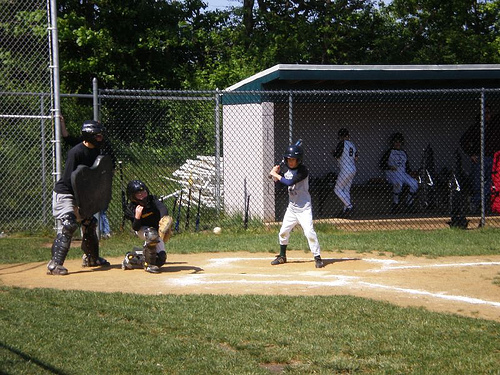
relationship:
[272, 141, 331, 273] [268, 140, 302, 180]
boy holding bat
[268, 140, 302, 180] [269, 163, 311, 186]
bat on right shoulder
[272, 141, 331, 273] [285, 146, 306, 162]
boy wears helmet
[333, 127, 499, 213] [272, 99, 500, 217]
baseball players in rest area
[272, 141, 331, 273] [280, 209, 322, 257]
boy wears pants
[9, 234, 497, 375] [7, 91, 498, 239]
field has fence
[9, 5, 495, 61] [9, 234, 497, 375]
trees behind field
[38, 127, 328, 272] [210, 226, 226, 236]
boys playing baseball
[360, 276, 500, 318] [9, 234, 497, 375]
lines drawn in ground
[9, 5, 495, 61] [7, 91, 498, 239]
trees behind fence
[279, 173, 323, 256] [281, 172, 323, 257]
players in white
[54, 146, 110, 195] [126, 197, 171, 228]
players dress in black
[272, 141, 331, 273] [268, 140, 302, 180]
boy swings baseballbat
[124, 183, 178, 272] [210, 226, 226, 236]
catcher waiting for ball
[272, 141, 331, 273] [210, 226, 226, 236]
boy playing baseball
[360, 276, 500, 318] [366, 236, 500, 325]
lines in dirt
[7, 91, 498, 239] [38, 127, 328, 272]
page fence behind players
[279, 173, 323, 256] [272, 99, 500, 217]
players in dugout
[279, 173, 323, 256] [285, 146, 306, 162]
players have helmet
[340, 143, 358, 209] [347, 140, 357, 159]
shirt with number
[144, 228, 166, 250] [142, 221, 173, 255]
skinpads for protection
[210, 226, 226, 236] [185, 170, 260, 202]
baseball sailing through air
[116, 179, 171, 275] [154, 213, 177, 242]
boy wearing glove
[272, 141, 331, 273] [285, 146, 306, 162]
boy wearing helmet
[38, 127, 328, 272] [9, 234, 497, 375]
baseball players on field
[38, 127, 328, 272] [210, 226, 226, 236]
people playing baseball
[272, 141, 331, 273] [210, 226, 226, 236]
batter miss theball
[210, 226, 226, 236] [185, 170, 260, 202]
ball in air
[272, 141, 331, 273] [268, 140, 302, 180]
boy holds bat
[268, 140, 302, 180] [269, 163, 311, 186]
bat over right shoulder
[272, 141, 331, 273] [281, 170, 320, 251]
boy wearing team shirt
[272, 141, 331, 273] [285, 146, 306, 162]
boy has helmet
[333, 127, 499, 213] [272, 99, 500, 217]
baseball players inside restarea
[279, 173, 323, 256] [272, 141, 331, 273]
players wears team uniform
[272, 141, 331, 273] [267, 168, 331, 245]
player wears uniform